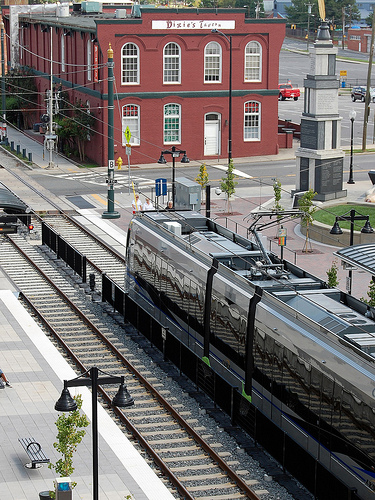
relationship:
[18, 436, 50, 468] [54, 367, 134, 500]
bench on light post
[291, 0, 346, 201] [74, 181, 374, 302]
statue on sidewalk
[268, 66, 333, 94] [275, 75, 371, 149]
truck in parking lot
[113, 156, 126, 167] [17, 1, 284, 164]
hydrants in front of building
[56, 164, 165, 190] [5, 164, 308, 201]
crosswalk on street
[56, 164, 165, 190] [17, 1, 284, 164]
crosswalk in front of building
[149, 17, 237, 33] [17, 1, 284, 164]
white sign on building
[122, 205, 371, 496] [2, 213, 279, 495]
train on tracks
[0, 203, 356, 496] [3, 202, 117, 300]
train tracks on ground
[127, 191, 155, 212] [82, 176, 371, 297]
people walking on sidewalk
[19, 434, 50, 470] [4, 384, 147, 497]
bench on sidewalk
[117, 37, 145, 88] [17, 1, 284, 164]
windows on building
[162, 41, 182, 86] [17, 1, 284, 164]
window on building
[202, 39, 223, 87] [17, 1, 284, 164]
windows on building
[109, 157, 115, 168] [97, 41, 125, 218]
b on post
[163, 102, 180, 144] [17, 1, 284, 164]
window on building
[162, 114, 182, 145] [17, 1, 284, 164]
window on building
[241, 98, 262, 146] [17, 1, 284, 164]
window on building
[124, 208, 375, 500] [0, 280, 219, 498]
train at platform